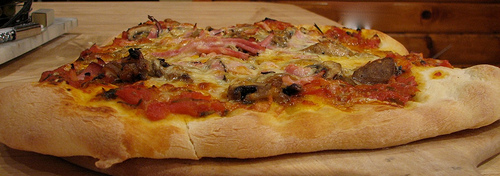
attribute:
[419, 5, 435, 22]
knot — brown 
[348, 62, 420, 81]
meat — large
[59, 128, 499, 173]
peel — wooden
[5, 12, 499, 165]
pizza — chopping, sliced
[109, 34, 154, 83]
meat — chunked, large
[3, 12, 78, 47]
board — marble, gray, white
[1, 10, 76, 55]
item — silver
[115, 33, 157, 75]
sausage — piece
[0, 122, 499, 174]
block — wooden